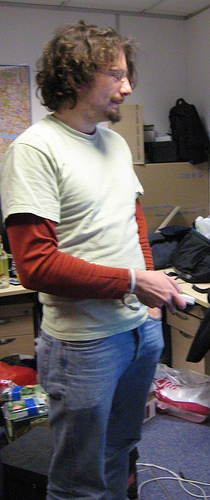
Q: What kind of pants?
A: Jeans.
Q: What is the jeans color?
A: Blue.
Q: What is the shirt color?
A: Cream.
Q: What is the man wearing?
A: Jeans.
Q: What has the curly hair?
A: The man.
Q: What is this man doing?
A: Holding a remote.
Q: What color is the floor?
A: Blue.